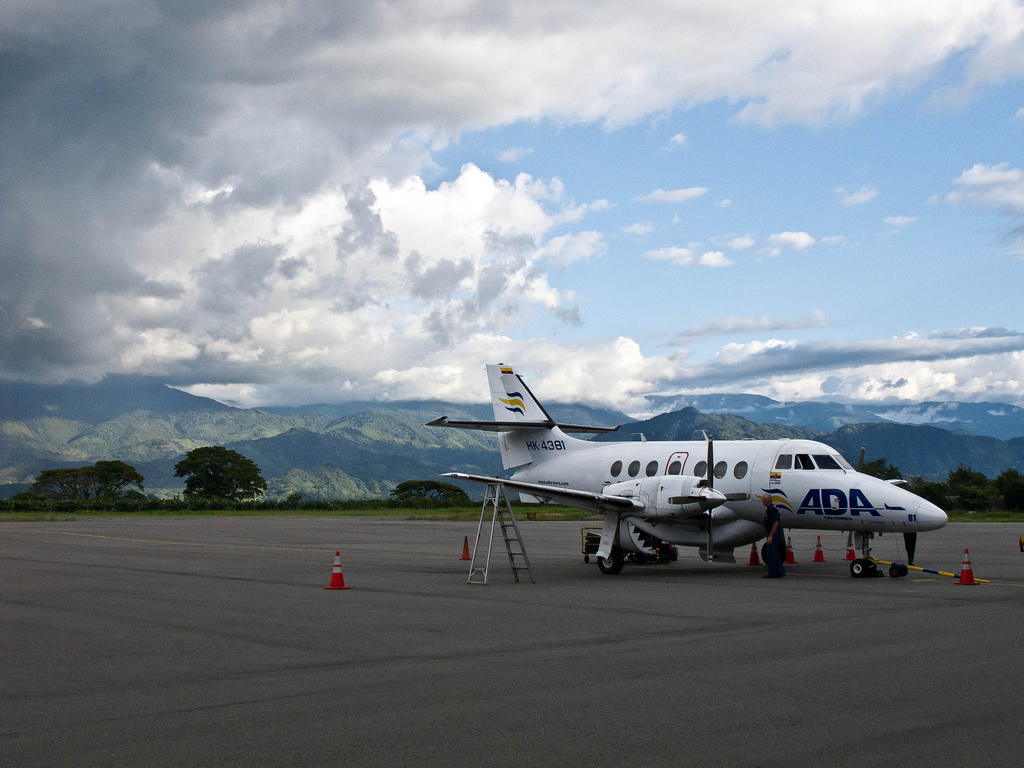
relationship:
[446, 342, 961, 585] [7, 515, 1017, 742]
plane on pavement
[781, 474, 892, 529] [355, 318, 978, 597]
letters on plane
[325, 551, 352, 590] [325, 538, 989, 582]
cone has stripes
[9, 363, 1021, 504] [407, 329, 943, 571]
mountain range behind plane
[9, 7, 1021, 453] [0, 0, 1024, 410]
cloud covering cloud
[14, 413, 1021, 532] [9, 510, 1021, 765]
trees behind pavement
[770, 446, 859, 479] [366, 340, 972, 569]
cockpit windows on plane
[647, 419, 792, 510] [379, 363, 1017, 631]
propeller on plane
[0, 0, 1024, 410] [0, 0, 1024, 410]
cloud in cloud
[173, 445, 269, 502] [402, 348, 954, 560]
trees behind plane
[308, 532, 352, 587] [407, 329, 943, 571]
cone next to plane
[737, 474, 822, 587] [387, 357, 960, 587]
person standing by plane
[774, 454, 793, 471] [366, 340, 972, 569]
cockpit windows on plane